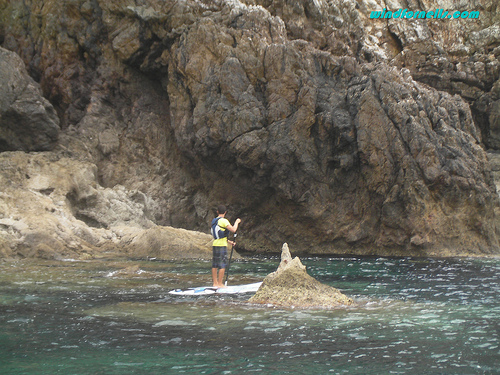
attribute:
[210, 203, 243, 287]
man — paddling, paddle boarding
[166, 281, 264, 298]
surfboard — white, white ad blue, blue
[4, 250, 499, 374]
river — dark blue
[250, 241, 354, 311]
rock — brown, protruding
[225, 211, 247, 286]
paddle — long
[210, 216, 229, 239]
life vest — blue, white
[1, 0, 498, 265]
formation — large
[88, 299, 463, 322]
sand bar — brown, small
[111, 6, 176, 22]
cliff — small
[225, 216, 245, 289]
oar — black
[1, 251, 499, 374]
water — greenish gray, shining, choppy, clear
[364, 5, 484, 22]
web address — green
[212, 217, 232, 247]
shirt — yellow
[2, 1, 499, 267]
hill — rock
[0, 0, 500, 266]
landscape — rocky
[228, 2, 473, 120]
cliff — rocky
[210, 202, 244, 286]
boy — paddle boarding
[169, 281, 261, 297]
paddle board — white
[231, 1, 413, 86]
outcroppings — pointed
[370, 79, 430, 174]
indentation — dark